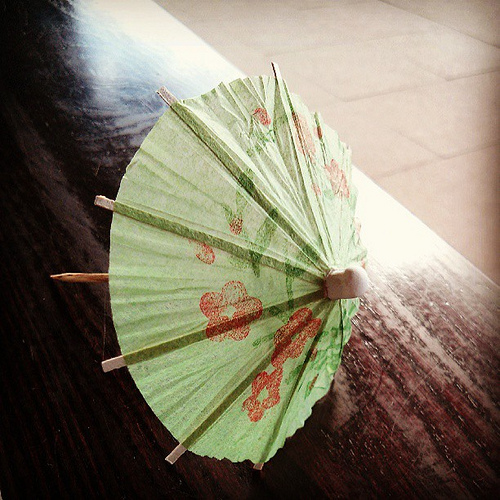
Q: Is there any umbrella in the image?
A: Yes, there is an umbrella.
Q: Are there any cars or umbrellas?
A: Yes, there is an umbrella.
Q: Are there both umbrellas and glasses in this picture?
A: No, there is an umbrella but no glasses.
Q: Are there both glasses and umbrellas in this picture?
A: No, there is an umbrella but no glasses.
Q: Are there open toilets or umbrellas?
A: Yes, there is an open umbrella.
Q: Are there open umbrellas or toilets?
A: Yes, there is an open umbrella.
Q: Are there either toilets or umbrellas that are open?
A: Yes, the umbrella is open.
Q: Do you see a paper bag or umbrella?
A: Yes, there is a paper umbrella.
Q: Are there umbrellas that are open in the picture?
A: Yes, there is an open umbrella.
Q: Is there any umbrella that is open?
A: Yes, there is an umbrella that is open.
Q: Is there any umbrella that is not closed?
A: Yes, there is a open umbrella.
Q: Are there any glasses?
A: No, there are no glasses.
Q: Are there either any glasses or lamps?
A: No, there are no glasses or lamps.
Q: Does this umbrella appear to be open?
A: Yes, the umbrella is open.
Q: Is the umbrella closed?
A: No, the umbrella is open.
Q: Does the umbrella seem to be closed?
A: No, the umbrella is open.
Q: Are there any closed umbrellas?
A: No, there is an umbrella but it is open.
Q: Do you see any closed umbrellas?
A: No, there is an umbrella but it is open.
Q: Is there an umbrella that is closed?
A: No, there is an umbrella but it is open.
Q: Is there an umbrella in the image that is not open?
A: No, there is an umbrella but it is open.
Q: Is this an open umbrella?
A: Yes, this is an open umbrella.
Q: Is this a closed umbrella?
A: No, this is an open umbrella.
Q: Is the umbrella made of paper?
A: Yes, the umbrella is made of paper.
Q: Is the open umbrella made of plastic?
A: No, the umbrella is made of paper.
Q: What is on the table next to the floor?
A: The umbrella is on the table.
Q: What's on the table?
A: The umbrella is on the table.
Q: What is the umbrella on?
A: The umbrella is on the table.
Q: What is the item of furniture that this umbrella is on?
A: The piece of furniture is a table.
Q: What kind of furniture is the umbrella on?
A: The umbrella is on the table.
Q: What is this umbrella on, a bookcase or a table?
A: The umbrella is on a table.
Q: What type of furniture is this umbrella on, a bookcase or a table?
A: The umbrella is on a table.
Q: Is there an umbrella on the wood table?
A: Yes, there is an umbrella on the table.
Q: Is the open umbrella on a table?
A: Yes, the umbrella is on a table.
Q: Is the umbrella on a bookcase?
A: No, the umbrella is on a table.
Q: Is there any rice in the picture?
A: No, there is no rice.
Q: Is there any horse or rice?
A: No, there are no rice or horses.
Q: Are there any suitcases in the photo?
A: No, there are no suitcases.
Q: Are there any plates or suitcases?
A: No, there are no suitcases or plates.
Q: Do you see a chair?
A: No, there are no chairs.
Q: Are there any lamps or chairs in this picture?
A: No, there are no chairs or lamps.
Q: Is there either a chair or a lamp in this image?
A: No, there are no chairs or lamps.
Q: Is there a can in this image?
A: No, there are no cans.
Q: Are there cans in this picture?
A: No, there are no cans.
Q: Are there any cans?
A: No, there are no cans.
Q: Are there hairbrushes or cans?
A: No, there are no cans or hairbrushes.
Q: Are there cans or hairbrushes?
A: No, there are no cans or hairbrushes.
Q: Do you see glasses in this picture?
A: No, there are no glasses.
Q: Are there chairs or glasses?
A: No, there are no glasses or chairs.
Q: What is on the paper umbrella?
A: The flowers are on the umbrella.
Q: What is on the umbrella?
A: The flowers are on the umbrella.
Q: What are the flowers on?
A: The flowers are on the umbrella.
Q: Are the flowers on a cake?
A: No, the flowers are on the umbrella.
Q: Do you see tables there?
A: Yes, there is a table.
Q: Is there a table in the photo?
A: Yes, there is a table.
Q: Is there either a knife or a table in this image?
A: Yes, there is a table.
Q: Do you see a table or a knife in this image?
A: Yes, there is a table.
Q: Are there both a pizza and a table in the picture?
A: No, there is a table but no pizzas.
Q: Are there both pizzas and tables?
A: No, there is a table but no pizzas.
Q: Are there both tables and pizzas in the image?
A: No, there is a table but no pizzas.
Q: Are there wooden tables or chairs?
A: Yes, there is a wood table.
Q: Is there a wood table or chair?
A: Yes, there is a wood table.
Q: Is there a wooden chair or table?
A: Yes, there is a wood table.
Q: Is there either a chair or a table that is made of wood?
A: Yes, the table is made of wood.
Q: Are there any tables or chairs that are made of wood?
A: Yes, the table is made of wood.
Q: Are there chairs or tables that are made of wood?
A: Yes, the table is made of wood.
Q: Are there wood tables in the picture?
A: Yes, there is a wood table.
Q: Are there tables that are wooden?
A: Yes, there is a table that is wooden.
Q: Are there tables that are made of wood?
A: Yes, there is a table that is made of wood.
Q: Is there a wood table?
A: Yes, there is a table that is made of wood.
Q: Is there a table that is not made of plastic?
A: Yes, there is a table that is made of wood.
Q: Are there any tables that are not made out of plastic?
A: Yes, there is a table that is made of wood.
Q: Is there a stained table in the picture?
A: Yes, there is a stained table.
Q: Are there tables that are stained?
A: Yes, there is a table that is stained.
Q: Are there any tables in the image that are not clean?
A: Yes, there is a stained table.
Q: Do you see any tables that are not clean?
A: Yes, there is a stained table.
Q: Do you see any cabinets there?
A: No, there are no cabinets.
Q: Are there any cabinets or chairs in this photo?
A: No, there are no cabinets or chairs.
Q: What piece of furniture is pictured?
A: The piece of furniture is a table.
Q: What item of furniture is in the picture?
A: The piece of furniture is a table.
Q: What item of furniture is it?
A: The piece of furniture is a table.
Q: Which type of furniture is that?
A: This is a table.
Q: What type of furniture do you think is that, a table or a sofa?
A: This is a table.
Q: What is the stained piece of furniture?
A: The piece of furniture is a table.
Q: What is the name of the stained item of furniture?
A: The piece of furniture is a table.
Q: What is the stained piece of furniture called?
A: The piece of furniture is a table.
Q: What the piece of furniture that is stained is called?
A: The piece of furniture is a table.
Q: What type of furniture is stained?
A: The furniture is a table.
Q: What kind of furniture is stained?
A: The furniture is a table.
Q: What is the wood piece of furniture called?
A: The piece of furniture is a table.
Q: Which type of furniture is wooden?
A: The furniture is a table.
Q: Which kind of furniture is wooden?
A: The furniture is a table.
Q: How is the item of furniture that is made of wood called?
A: The piece of furniture is a table.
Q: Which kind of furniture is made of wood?
A: The furniture is a table.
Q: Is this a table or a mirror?
A: This is a table.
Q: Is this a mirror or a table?
A: This is a table.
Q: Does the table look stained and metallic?
A: No, the table is stained but wooden.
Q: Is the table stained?
A: Yes, the table is stained.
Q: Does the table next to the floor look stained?
A: Yes, the table is stained.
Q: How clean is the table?
A: The table is stained.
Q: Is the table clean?
A: No, the table is stained.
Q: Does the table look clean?
A: No, the table is stained.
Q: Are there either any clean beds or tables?
A: No, there is a table but it is stained.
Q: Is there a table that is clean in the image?
A: No, there is a table but it is stained.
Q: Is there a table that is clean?
A: No, there is a table but it is stained.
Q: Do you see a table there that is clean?
A: No, there is a table but it is stained.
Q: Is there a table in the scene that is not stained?
A: No, there is a table but it is stained.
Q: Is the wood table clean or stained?
A: The table is stained.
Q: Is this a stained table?
A: Yes, this is a stained table.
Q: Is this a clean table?
A: No, this is a stained table.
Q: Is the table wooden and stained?
A: Yes, the table is wooden and stained.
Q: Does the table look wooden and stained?
A: Yes, the table is wooden and stained.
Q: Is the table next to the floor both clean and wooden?
A: No, the table is wooden but stained.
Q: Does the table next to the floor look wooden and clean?
A: No, the table is wooden but stained.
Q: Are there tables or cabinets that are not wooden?
A: No, there is a table but it is wooden.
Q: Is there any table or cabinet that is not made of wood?
A: No, there is a table but it is made of wood.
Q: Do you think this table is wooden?
A: Yes, the table is wooden.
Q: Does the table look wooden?
A: Yes, the table is wooden.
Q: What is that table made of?
A: The table is made of wood.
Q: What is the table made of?
A: The table is made of wood.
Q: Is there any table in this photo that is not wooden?
A: No, there is a table but it is wooden.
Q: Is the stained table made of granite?
A: No, the table is made of wood.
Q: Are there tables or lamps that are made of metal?
A: No, there is a table but it is made of wood.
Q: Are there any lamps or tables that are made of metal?
A: No, there is a table but it is made of wood.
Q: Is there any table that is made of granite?
A: No, there is a table but it is made of wood.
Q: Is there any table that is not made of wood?
A: No, there is a table but it is made of wood.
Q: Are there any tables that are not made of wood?
A: No, there is a table but it is made of wood.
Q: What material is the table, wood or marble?
A: The table is made of wood.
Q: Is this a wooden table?
A: Yes, this is a wooden table.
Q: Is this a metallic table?
A: No, this is a wooden table.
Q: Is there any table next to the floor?
A: Yes, there is a table next to the floor.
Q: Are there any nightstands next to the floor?
A: No, there is a table next to the floor.